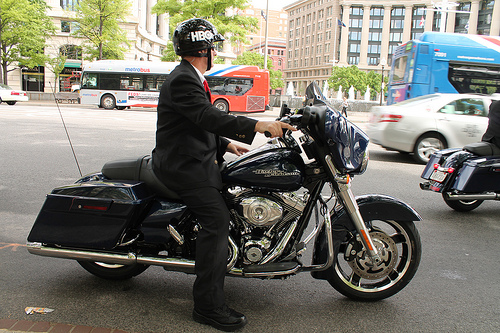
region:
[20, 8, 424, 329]
A man on a motorcycle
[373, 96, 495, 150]
the car is silver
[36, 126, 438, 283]
the bike is black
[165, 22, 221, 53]
the helmet is black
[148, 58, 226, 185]
the jacket is black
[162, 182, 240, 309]
the pant is black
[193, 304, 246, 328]
the shoe is black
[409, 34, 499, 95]
the bus is blue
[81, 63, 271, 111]
the bus is red and white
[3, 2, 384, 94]
the trees are at the background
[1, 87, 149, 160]
the road is tarmaced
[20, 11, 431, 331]
person on a motorcycle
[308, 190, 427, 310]
front wheel on a motorcycle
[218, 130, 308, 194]
gas tank on a motorcycle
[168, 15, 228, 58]
helmet on a persons head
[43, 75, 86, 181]
antenna on a motorcycle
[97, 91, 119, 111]
front wheel on a bus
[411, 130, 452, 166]
rear wheel on a vehicle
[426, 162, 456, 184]
rear licence plate on a motorcycle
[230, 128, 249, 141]
buttons on a persons coat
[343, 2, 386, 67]
windows on a building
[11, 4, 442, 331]
man on a motorbike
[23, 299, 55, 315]
trash on the ground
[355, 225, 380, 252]
orange reflector on the piece of metal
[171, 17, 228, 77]
black helmet on the head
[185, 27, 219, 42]
white writing on the helmet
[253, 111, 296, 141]
fingers curled around the handlebar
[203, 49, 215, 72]
black strap around the chin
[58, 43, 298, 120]
bus on the road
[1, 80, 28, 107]
back end of a white car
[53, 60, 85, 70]
green awning on the building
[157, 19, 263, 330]
man wearing a business suit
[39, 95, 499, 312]
two black motorcycles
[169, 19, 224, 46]
black helmet the rider is wearing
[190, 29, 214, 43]
white lettering on the black helmet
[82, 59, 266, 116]
white and red bus on the street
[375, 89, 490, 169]
silver car driving on the street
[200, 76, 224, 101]
red necktie man is wearing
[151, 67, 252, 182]
black suit jacket man is wearing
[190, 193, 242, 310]
black dress pants the man is wearing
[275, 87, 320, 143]
handlebars on the motorcycle